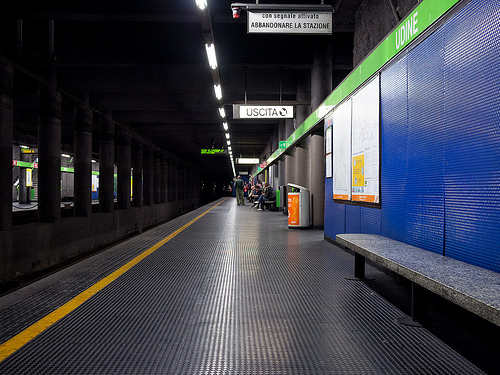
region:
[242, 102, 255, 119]
black letter on sign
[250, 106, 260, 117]
black letter on sign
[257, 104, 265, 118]
black letter on sign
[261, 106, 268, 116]
black letter on sign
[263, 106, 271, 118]
black letter on sign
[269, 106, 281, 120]
black letter on sign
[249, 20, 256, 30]
black letter on sign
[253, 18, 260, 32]
black letter on sign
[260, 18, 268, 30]
black letter on sign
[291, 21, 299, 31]
black letter on sign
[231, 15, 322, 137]
signs hanging from a ceiling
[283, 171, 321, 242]
a trashcan sitting in front of a entrance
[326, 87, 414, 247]
a map displayed on a wall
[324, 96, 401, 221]
a wall displaying a map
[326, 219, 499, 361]
an empty bench sitting in front of a wall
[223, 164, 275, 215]
people gathered in a subway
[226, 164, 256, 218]
a person standing in a subway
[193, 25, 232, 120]
lights hanging from a ceiling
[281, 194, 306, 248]
an orange sign displayed on a trashcan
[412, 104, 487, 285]
a blue wall standing behind a bench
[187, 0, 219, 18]
light on the ceiling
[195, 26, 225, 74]
light on the ceiling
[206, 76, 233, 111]
light on the ceiling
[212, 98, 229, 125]
light on the ceiling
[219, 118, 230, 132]
light on the ceiling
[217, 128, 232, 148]
light on the ceiling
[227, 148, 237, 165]
light on the ceiling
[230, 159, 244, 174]
light on the ceiling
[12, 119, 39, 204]
window of a train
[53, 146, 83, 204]
window of a train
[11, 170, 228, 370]
empty subway train platform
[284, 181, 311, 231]
one metal orange and white garbage can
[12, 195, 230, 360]
yellow line along train platform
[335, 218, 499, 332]
one long gray bench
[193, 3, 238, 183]
row of illuminated fluorescent lights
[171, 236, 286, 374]
black textured train station floor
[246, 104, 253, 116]
one black capital letter U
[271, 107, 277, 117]
one black capital letter A on white background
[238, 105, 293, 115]
White sign that says "USCITA".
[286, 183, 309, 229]
Orange and white trash can.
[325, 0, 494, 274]
The wall is blue.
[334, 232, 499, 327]
Closest bench with no one sitting on it.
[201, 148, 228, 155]
Sign with neon green lettering.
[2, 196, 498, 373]
The train platform is black with a yellow stripe.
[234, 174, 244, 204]
Man standing up waiting for the train.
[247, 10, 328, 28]
White sign with words "con segnale arrivals".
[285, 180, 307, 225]
White trashcan with orange label.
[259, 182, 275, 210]
Closest person sitting on a bench.